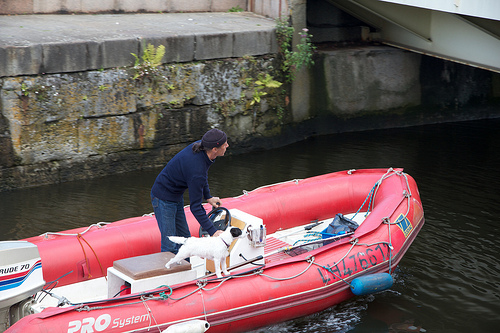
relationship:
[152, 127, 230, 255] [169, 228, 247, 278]
man to left of dog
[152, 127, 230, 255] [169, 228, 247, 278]
man touching dog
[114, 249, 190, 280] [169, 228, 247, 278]
cushion touching dog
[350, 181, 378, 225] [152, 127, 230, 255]
rope right of man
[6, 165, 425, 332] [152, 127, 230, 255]
boat supporting man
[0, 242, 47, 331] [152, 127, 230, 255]
engine behind man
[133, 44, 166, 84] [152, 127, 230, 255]
weeds are behind man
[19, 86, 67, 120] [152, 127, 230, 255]
mold behind man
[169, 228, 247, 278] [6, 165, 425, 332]
dog on boat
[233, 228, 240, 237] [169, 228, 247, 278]
ear on dog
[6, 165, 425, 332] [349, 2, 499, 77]
boat passing under bridge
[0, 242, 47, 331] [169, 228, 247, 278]
engine behind dog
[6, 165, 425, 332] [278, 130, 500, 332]
boat on water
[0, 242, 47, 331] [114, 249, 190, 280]
engine behind cushion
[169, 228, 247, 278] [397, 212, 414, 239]
dog behind sign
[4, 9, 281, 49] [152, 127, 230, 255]
platform above man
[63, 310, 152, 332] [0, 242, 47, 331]
writing beneath engine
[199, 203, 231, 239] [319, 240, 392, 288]
wheel above number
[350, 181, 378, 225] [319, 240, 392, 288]
rope above number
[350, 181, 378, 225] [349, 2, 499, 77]
rope beneath bridge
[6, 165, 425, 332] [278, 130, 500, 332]
boat moving on water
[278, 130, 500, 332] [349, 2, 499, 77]
water beneath bridge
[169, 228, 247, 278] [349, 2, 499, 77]
dog beneath bridge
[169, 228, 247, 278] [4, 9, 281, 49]
dog beneath platform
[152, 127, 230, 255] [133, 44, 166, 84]
man beneath weeds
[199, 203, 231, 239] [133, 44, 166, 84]
wheel beneath weeds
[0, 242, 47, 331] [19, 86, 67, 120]
engine beneath mold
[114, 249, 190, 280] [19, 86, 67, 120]
cushion beneath mold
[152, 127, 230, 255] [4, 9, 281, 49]
man beneath platform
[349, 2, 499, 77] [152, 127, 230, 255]
bridge above man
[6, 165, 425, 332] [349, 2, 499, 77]
boat moving towards bridge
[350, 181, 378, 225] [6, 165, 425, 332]
rope tied to boat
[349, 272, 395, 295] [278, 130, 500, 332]
buoy near water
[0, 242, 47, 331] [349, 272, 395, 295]
engine to left of buoy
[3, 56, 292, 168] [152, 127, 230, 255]
brick to left of man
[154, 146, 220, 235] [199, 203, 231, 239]
sweater above wheel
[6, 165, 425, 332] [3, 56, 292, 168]
boat beneath brick